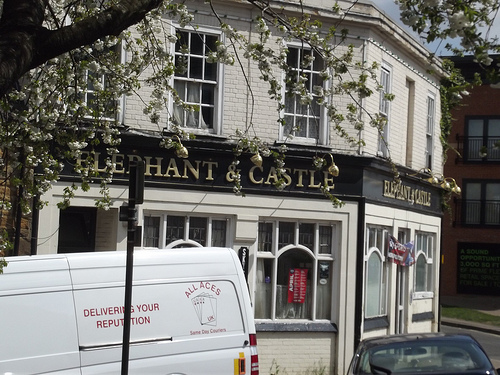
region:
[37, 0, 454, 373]
Building is on corner lot.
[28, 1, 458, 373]
Building front is constructed with brick.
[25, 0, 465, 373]
Building front is all white.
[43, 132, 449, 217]
Sign on building says ELEPHANT & CASTLE.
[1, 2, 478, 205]
Tree has white blossoms.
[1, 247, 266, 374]
Van parked in front of building.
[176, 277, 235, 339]
Side of van says, ALL ACES.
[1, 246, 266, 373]
Cargo van is white.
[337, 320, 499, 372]
There is a car behind the van.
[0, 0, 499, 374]
The picture was taken during daytime hours.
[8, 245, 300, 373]
white large delivering van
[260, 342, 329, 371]
white brick bottom of building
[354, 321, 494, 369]
parked black sedan in front of store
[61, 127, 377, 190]
elephant castle sign in front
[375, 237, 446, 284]
American flag hanging on the window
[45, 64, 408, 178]
white flowers on tree branches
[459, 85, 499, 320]
red brick building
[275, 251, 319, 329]
red and white sports dates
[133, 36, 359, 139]
white large opened windows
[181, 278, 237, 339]
all aces card logo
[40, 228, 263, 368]
white van in front of commercial establishment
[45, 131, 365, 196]
gold lettering on black background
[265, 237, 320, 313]
red sign on arch glass panel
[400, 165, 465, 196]
curved gold lights hanging over sign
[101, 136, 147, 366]
black pole in front of van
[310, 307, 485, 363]
car parked in front of building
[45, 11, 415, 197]
branches with white blossoms hanging down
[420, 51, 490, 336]
brick building on other side of street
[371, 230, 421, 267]
banner hanging over doorway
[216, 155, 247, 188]
ampersand in middle of names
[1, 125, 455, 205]
sign with the name of the shop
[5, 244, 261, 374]
side of a delivery van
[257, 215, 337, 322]
window of the shop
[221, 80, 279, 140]
brick section of the building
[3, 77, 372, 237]
cherry blossoms in front of the building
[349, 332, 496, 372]
a dark colored car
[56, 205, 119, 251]
A doorway into the building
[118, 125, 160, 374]
A black pole out in front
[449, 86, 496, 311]
another building in the backtround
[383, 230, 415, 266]
A flag on the side of the building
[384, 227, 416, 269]
Flag banner on the right side of the building.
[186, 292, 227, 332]
Card design on the side of the vehicle.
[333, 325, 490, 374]
Black car in front of the building.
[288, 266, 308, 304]
Red sign with white lettering in the window of the building.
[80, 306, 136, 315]
Red letter word starting with D on the side of the white vehicle.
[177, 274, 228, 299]
Letters above the card design on the white vehicle.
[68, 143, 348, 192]
Name of the store in the front of the store in white letters.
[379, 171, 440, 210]
Name of the store on the side of the building in white letters.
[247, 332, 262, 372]
Tail light on the white vehicle.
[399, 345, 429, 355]
The rear view mirror inside of the black vehicle.